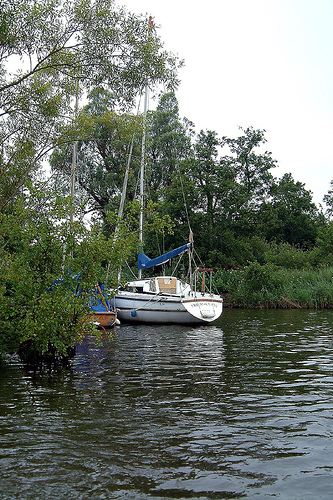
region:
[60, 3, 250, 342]
this is a boat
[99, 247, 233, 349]
the boat is white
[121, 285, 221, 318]
brown trim on boat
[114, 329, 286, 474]
the water is green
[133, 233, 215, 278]
blue pole on boat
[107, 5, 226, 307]
tall poles on boat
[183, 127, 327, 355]
lush greenery in background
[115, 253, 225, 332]
the boat is white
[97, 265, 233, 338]
the boat is white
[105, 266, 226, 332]
the boat is white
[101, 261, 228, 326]
the boat is white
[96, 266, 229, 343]
the boat is white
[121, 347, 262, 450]
the water is murky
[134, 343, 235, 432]
the water is murky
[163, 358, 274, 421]
the water is murky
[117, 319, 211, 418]
the water is murky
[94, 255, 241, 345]
boat in the water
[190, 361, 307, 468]
light hitting the water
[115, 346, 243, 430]
ripples in the water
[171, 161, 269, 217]
trees near the boat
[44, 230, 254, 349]
boats in the water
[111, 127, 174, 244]
pole on the boat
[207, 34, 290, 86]
sky above the land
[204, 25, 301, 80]
sky with no clouds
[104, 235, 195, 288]
blue part of boat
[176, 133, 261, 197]
branches on the tree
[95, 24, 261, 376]
this is a sailboat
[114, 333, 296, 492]
the water is green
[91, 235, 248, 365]
the boat is white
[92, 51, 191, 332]
poles for the sails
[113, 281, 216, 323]
brown trim on boat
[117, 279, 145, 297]
window on the boat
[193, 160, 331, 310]
a lush wooded area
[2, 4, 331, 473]
a bright and clear day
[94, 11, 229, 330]
a white boat in a swamp river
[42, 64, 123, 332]
a small rusty red sailboat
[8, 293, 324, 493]
a marshy dark river